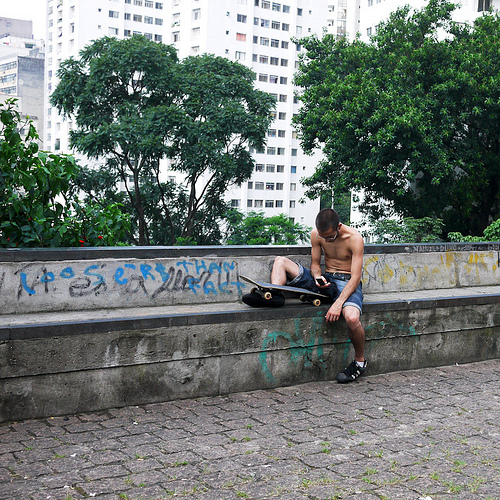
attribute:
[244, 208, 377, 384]
man — shirtless, sitting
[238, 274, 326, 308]
skateboard — black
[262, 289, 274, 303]
wheel — yellow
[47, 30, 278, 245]
tree — tall, large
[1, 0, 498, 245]
buildings — big, white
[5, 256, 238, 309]
grafitti — orange, blue, black, large, dark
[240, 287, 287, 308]
shoe — tennis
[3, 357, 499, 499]
ground — dark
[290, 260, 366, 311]
shorts — blue